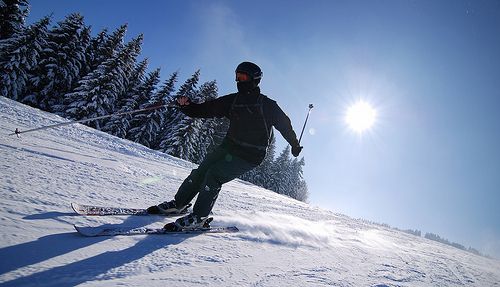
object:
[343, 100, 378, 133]
sun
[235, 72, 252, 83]
goggles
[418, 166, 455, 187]
ground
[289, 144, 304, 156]
hand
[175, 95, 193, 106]
hand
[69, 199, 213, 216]
ski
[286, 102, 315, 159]
poles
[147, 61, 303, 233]
man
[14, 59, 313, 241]
skiing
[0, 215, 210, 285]
shadow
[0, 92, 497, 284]
snow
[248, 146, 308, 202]
trees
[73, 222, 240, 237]
ski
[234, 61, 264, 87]
helmet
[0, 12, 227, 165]
trees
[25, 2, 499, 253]
sky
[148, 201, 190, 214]
ski boot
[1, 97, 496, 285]
ground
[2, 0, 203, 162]
snow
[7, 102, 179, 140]
pole